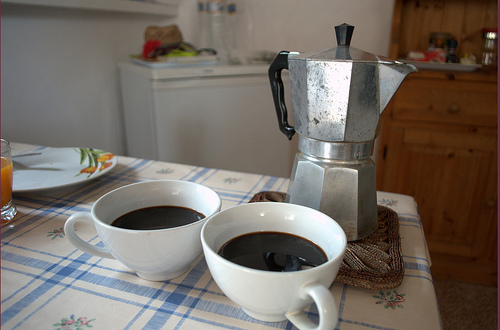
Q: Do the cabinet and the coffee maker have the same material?
A: No, the cabinet is made of wood and the coffee maker is made of metal.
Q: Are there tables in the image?
A: Yes, there is a table.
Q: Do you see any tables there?
A: Yes, there is a table.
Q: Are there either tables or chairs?
A: Yes, there is a table.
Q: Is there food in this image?
A: No, there is no food.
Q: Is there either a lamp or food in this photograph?
A: No, there are no food or lamps.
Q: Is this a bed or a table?
A: This is a table.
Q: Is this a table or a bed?
A: This is a table.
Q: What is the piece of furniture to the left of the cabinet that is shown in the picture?
A: The piece of furniture is a table.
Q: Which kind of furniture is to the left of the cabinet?
A: The piece of furniture is a table.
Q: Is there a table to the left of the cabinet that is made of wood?
A: Yes, there is a table to the left of the cabinet.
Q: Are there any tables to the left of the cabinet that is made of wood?
A: Yes, there is a table to the left of the cabinet.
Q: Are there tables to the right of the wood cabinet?
A: No, the table is to the left of the cabinet.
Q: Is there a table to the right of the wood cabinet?
A: No, the table is to the left of the cabinet.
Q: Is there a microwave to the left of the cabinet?
A: No, there is a table to the left of the cabinet.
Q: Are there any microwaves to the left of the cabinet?
A: No, there is a table to the left of the cabinet.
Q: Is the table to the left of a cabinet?
A: Yes, the table is to the left of a cabinet.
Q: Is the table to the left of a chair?
A: No, the table is to the left of a cabinet.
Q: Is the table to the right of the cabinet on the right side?
A: No, the table is to the left of the cabinet.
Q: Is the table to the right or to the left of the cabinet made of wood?
A: The table is to the left of the cabinet.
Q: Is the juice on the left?
A: Yes, the juice is on the left of the image.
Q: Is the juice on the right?
A: No, the juice is on the left of the image.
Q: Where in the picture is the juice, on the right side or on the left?
A: The juice is on the left of the image.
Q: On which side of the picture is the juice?
A: The juice is on the left of the image.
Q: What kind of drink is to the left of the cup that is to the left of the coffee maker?
A: The drink is juice.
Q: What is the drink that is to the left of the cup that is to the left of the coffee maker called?
A: The drink is juice.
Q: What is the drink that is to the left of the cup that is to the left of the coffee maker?
A: The drink is juice.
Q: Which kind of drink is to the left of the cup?
A: The drink is juice.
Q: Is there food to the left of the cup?
A: No, there is juice to the left of the cup.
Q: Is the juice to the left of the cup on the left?
A: Yes, the juice is to the left of the cup.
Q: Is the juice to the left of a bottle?
A: No, the juice is to the left of the cup.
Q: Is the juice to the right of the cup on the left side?
A: No, the juice is to the left of the cup.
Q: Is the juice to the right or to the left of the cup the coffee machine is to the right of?
A: The juice is to the left of the cup.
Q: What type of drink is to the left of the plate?
A: The drink is juice.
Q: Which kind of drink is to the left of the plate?
A: The drink is juice.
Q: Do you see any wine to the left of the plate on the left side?
A: No, there is juice to the left of the plate.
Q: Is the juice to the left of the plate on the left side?
A: Yes, the juice is to the left of the plate.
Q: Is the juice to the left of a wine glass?
A: No, the juice is to the left of the plate.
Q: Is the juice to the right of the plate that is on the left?
A: No, the juice is to the left of the plate.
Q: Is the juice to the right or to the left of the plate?
A: The juice is to the left of the plate.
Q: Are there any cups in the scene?
A: Yes, there is a cup.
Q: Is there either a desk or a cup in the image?
A: Yes, there is a cup.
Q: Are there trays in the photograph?
A: No, there are no trays.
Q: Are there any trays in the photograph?
A: No, there are no trays.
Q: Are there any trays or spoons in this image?
A: No, there are no trays or spoons.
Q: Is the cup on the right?
A: No, the cup is on the left of the image.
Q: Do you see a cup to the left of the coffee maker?
A: Yes, there is a cup to the left of the coffee maker.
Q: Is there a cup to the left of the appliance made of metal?
A: Yes, there is a cup to the left of the coffee maker.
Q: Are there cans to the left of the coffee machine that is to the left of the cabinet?
A: No, there is a cup to the left of the coffee maker.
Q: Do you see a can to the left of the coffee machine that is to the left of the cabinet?
A: No, there is a cup to the left of the coffee maker.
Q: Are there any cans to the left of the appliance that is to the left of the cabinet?
A: No, there is a cup to the left of the coffee maker.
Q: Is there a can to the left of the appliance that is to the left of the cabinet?
A: No, there is a cup to the left of the coffee maker.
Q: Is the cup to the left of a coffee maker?
A: Yes, the cup is to the left of a coffee maker.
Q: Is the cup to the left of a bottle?
A: No, the cup is to the left of a coffee maker.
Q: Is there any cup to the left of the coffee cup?
A: Yes, there is a cup to the left of the coffee cup.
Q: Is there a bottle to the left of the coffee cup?
A: No, there is a cup to the left of the coffee cup.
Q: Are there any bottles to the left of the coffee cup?
A: No, there is a cup to the left of the coffee cup.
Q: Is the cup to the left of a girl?
A: No, the cup is to the left of the coffee cup.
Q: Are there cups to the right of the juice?
A: Yes, there is a cup to the right of the juice.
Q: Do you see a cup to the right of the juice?
A: Yes, there is a cup to the right of the juice.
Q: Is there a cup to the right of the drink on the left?
A: Yes, there is a cup to the right of the juice.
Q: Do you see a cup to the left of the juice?
A: No, the cup is to the right of the juice.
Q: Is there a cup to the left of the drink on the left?
A: No, the cup is to the right of the juice.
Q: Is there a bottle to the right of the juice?
A: No, there is a cup to the right of the juice.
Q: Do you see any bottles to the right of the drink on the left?
A: No, there is a cup to the right of the juice.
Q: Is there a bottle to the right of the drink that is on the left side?
A: No, there is a cup to the right of the juice.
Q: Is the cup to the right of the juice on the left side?
A: Yes, the cup is to the right of the juice.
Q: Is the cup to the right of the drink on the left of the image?
A: Yes, the cup is to the right of the juice.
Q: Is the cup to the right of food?
A: No, the cup is to the right of the juice.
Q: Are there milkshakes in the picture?
A: No, there are no milkshakes.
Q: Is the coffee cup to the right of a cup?
A: Yes, the coffee cup is to the right of a cup.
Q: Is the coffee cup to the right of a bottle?
A: No, the coffee cup is to the right of a cup.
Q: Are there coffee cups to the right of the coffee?
A: Yes, there is a coffee cup to the right of the coffee.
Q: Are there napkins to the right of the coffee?
A: No, there is a coffee cup to the right of the coffee.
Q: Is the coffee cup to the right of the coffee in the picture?
A: Yes, the coffee cup is to the right of the coffee.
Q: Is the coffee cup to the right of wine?
A: No, the coffee cup is to the right of the coffee.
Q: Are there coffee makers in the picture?
A: Yes, there is a coffee maker.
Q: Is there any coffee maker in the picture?
A: Yes, there is a coffee maker.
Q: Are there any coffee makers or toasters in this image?
A: Yes, there is a coffee maker.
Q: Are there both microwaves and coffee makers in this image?
A: No, there is a coffee maker but no microwaves.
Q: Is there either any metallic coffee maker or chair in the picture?
A: Yes, there is a metal coffee maker.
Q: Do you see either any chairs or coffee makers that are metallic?
A: Yes, the coffee maker is metallic.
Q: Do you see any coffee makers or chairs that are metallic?
A: Yes, the coffee maker is metallic.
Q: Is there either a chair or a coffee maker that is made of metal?
A: Yes, the coffee maker is made of metal.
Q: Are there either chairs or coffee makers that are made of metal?
A: Yes, the coffee maker is made of metal.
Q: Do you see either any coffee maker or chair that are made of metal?
A: Yes, the coffee maker is made of metal.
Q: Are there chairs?
A: No, there are no chairs.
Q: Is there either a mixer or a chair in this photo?
A: No, there are no chairs or mixers.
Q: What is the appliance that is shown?
A: The appliance is a coffee maker.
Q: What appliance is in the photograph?
A: The appliance is a coffee maker.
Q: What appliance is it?
A: The appliance is a coffee maker.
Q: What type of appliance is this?
A: This is a coffee maker.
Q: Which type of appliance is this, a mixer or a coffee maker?
A: This is a coffee maker.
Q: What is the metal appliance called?
A: The appliance is a coffee maker.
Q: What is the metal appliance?
A: The appliance is a coffee maker.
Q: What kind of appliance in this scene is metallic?
A: The appliance is a coffee maker.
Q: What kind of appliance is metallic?
A: The appliance is a coffee maker.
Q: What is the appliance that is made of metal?
A: The appliance is a coffee maker.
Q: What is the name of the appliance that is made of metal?
A: The appliance is a coffee maker.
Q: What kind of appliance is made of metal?
A: The appliance is a coffee maker.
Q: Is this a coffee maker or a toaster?
A: This is a coffee maker.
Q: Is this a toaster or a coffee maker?
A: This is a coffee maker.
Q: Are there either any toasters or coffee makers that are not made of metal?
A: No, there is a coffee maker but it is made of metal.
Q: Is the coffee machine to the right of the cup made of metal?
A: Yes, the coffee machine is made of metal.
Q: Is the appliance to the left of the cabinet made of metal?
A: Yes, the coffee machine is made of metal.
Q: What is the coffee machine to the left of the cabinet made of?
A: The coffee maker is made of metal.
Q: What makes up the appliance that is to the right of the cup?
A: The coffee maker is made of metal.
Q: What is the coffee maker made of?
A: The coffee maker is made of metal.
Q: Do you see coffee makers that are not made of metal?
A: No, there is a coffee maker but it is made of metal.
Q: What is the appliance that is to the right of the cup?
A: The appliance is a coffee maker.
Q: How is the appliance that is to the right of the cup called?
A: The appliance is a coffee maker.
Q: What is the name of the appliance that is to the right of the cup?
A: The appliance is a coffee maker.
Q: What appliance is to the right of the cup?
A: The appliance is a coffee maker.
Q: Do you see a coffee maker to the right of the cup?
A: Yes, there is a coffee maker to the right of the cup.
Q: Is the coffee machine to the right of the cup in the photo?
A: Yes, the coffee machine is to the right of the cup.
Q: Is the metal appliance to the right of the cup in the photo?
A: Yes, the coffee machine is to the right of the cup.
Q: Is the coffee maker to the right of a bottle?
A: No, the coffee maker is to the right of the cup.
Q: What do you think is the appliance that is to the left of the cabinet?
A: The appliance is a coffee maker.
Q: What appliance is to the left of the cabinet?
A: The appliance is a coffee maker.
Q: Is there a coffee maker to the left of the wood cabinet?
A: Yes, there is a coffee maker to the left of the cabinet.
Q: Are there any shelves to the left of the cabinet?
A: No, there is a coffee maker to the left of the cabinet.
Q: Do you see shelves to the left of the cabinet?
A: No, there is a coffee maker to the left of the cabinet.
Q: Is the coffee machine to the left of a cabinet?
A: Yes, the coffee machine is to the left of a cabinet.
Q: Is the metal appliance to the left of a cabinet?
A: Yes, the coffee machine is to the left of a cabinet.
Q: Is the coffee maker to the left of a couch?
A: No, the coffee maker is to the left of a cabinet.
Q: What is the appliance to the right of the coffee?
A: The appliance is a coffee maker.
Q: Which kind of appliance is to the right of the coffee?
A: The appliance is a coffee maker.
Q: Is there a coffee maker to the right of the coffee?
A: Yes, there is a coffee maker to the right of the coffee.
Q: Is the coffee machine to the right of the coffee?
A: Yes, the coffee machine is to the right of the coffee.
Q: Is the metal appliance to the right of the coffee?
A: Yes, the coffee machine is to the right of the coffee.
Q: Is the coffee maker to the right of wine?
A: No, the coffee maker is to the right of the coffee.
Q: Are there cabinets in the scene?
A: Yes, there is a cabinet.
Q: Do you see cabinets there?
A: Yes, there is a cabinet.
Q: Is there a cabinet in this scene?
A: Yes, there is a cabinet.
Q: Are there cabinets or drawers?
A: Yes, there is a cabinet.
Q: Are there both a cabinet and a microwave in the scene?
A: No, there is a cabinet but no microwaves.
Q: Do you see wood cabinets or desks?
A: Yes, there is a wood cabinet.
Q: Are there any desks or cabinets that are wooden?
A: Yes, the cabinet is wooden.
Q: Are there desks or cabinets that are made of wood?
A: Yes, the cabinet is made of wood.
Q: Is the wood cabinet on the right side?
A: Yes, the cabinet is on the right of the image.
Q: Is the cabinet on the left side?
A: No, the cabinet is on the right of the image.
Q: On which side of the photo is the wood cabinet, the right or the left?
A: The cabinet is on the right of the image.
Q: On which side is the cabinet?
A: The cabinet is on the right of the image.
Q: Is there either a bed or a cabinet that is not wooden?
A: No, there is a cabinet but it is wooden.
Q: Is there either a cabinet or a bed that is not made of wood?
A: No, there is a cabinet but it is made of wood.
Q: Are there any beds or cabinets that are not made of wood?
A: No, there is a cabinet but it is made of wood.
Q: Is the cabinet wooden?
A: Yes, the cabinet is wooden.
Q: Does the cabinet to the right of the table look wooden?
A: Yes, the cabinet is wooden.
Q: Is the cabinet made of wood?
A: Yes, the cabinet is made of wood.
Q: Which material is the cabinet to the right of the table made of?
A: The cabinet is made of wood.